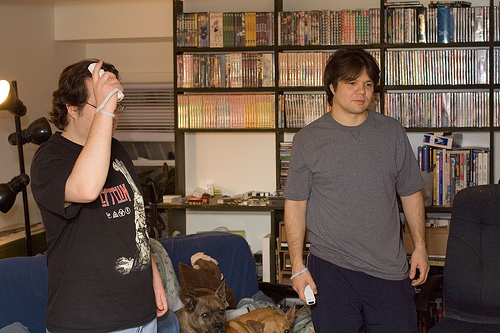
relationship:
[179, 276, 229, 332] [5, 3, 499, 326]
dog in room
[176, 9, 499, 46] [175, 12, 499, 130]
rows of books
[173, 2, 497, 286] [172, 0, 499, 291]
bookcase occupying space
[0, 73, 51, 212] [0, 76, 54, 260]
three light fixtures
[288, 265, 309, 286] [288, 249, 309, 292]
strap around wrist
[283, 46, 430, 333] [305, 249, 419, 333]
man wearing sweats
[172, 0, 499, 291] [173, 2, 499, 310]
shelf on wall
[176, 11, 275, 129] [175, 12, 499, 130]
neatly arranged books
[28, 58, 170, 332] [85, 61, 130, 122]
man playing wii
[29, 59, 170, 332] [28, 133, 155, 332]
man in t-shirt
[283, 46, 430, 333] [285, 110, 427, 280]
man in t-shirt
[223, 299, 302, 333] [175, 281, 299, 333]
dog laying down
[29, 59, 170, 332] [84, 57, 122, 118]
man holding controller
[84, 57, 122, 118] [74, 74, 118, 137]
controller by face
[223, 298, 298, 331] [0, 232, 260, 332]
dog on couch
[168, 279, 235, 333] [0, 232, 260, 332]
dog on couch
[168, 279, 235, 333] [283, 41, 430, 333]
dog between man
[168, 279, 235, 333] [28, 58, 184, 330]
dog between men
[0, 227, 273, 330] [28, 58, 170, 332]
sofa behind man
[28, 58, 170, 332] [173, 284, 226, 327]
man with dog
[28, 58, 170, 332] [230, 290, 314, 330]
man with clothes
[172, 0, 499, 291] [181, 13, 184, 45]
shelf filled with object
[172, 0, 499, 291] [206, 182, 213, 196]
shelf filled with object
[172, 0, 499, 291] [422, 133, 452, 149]
shelf filled with object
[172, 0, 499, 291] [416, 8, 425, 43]
shelf filled with object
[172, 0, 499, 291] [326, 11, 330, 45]
shelf filled with object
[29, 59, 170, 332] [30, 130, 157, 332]
man in t shirt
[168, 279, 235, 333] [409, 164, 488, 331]
dog laying on couch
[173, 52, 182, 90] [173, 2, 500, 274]
dvds on a bookcase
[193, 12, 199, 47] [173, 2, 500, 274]
dvds on a bookcase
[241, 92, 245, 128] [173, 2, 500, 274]
dvds on a bookcase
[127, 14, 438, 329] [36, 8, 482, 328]
inside a house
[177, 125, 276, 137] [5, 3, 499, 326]
shelf in room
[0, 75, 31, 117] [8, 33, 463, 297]
lamp for room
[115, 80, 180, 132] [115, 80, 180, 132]
blinds with blinds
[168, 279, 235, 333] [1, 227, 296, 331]
dog on couch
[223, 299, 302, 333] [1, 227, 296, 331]
dog on couch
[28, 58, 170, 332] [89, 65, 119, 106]
man standing while playing game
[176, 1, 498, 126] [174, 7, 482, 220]
books on shelf